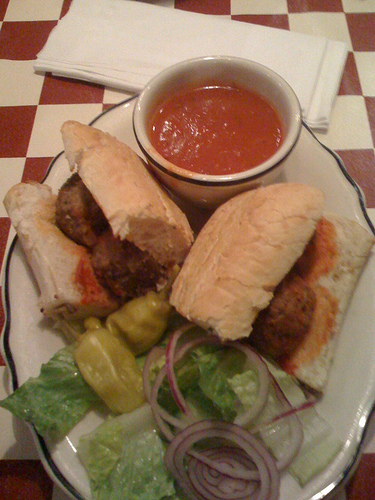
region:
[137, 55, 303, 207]
Bowl of tomato sauce.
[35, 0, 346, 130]
Stack of white napkins.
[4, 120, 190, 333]
Left half of a meatball sub sandwich.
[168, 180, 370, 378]
Right half of a meatball sub sandwich.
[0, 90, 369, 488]
White plate with black trim.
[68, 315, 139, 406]
Green pepper on the left.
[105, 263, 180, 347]
Green pepper on the right.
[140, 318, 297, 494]
Slices of purple onion.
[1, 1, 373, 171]
The table cloth is red and white checkers.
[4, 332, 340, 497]
Slices of lettuce on a plate.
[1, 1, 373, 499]
red and white checkered tablecloth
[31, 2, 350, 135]
white dinner napkins on tablecloth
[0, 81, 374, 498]
white plate with black trim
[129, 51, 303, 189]
round white dipping bowl with black trim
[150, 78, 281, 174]
Italian sauce for meatballs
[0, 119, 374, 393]
meatball sandwich cut in half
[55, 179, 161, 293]
meatballs on one half of sandwich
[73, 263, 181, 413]
pepperoncini peppers on plate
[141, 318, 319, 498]
slices of red onion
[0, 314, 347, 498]
pieces of green lettuce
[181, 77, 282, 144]
sauce in a cup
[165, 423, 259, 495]
onions on a plate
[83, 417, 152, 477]
lettuce on a plate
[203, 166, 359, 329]
bread on the plate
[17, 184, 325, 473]
many pieces of food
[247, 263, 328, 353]
meatball in the bread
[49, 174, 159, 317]
two pieces of meat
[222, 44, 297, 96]
cup with sauce inside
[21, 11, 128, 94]
napkins next to plate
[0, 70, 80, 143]
red and white tablecloth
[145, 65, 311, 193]
red sauce for meatball sandwhich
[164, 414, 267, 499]
red onions on a plate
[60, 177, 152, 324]
a meatball sandwich on a plate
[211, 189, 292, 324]
a piece of bread on a plate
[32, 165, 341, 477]
a sandwich and salad on a plate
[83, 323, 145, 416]
a jalapeno on a plate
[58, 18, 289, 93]
a napkin on a plate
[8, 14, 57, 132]
a checkered place mat for a table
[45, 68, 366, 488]
a large plate of food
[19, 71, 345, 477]
a plate of food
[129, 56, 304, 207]
A cup with red sauce.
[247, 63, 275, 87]
Part of a small cup.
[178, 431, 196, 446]
part of a red onion.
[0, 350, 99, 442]
A piece of green lettuce.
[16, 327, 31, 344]
Part of the plate.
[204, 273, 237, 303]
Part of the bread.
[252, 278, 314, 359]
Part of a meatball.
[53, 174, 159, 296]
Two meatballs on the bread.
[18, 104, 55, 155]
Part of the table.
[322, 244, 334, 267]
Part of the red sauce.